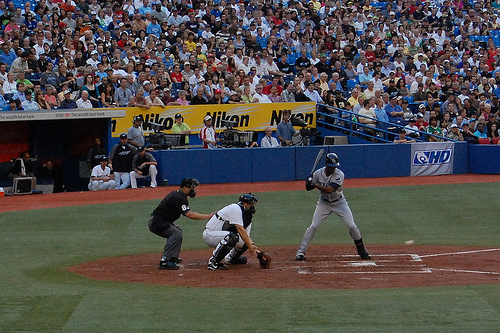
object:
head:
[236, 192, 259, 210]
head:
[179, 177, 200, 197]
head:
[118, 133, 130, 143]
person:
[108, 133, 153, 190]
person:
[88, 157, 116, 191]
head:
[99, 156, 109, 168]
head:
[80, 90, 90, 100]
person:
[74, 89, 92, 109]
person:
[43, 84, 56, 104]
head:
[46, 86, 52, 95]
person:
[11, 50, 36, 72]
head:
[19, 50, 31, 62]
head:
[6, 71, 14, 82]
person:
[2, 72, 21, 94]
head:
[237, 48, 243, 56]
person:
[233, 48, 246, 69]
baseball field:
[0, 0, 499, 328]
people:
[189, 87, 207, 106]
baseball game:
[145, 145, 374, 270]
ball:
[405, 239, 414, 246]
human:
[147, 178, 217, 270]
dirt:
[351, 254, 369, 270]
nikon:
[136, 110, 311, 130]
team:
[15, 126, 163, 190]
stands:
[0, 0, 485, 143]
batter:
[295, 152, 372, 261]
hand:
[250, 244, 258, 257]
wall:
[145, 150, 408, 186]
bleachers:
[0, 0, 499, 189]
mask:
[186, 185, 198, 199]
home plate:
[349, 259, 378, 267]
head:
[325, 152, 340, 168]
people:
[129, 89, 152, 109]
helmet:
[324, 153, 341, 169]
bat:
[308, 149, 325, 175]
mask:
[242, 197, 256, 210]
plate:
[348, 258, 379, 267]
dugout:
[2, 119, 113, 188]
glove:
[256, 251, 272, 269]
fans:
[0, 1, 497, 143]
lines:
[299, 265, 328, 277]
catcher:
[203, 192, 261, 272]